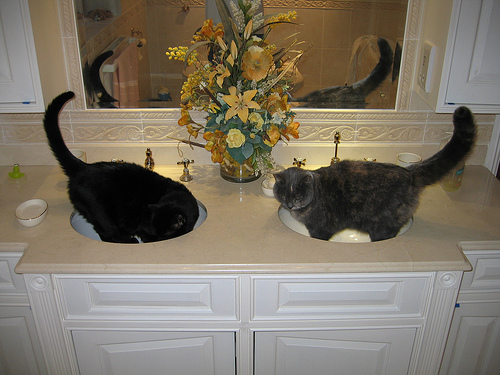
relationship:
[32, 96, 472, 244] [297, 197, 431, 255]
cats in sink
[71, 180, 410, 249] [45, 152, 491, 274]
sinks on counter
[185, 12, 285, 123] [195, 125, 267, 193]
flowers in vase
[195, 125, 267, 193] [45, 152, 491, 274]
vase on counter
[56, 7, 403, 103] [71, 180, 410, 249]
mirror above sinks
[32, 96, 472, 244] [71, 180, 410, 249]
cats in sinks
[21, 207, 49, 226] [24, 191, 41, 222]
bowl holds soap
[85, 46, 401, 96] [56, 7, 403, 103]
tails in mirror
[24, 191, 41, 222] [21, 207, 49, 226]
soap in bowl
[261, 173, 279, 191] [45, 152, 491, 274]
cup on counter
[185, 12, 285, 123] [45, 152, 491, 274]
flowers on counter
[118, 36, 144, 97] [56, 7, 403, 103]
towel reflects in mirror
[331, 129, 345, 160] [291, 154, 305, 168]
faucet next to handle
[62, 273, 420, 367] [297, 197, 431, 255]
cabinet under sink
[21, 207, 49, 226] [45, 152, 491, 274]
bowl on counter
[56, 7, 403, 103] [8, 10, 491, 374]
mirror in bathroom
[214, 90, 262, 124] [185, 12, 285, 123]
lily in flowers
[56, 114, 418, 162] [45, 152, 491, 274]
trim over counter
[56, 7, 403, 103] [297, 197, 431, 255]
mirror over sink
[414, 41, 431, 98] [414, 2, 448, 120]
outlet on wall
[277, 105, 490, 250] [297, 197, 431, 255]
cat in sink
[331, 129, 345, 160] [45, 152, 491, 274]
faucet on counter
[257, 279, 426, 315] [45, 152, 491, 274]
drawer under counter